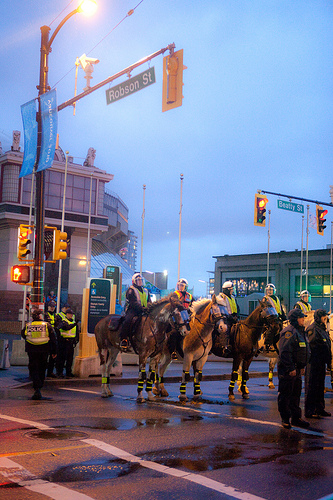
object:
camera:
[74, 51, 99, 76]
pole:
[26, 23, 53, 316]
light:
[74, 0, 105, 25]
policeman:
[123, 273, 149, 355]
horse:
[95, 293, 188, 405]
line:
[0, 408, 262, 500]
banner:
[16, 94, 38, 179]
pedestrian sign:
[9, 263, 36, 286]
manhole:
[20, 422, 94, 442]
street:
[1, 376, 331, 499]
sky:
[185, 3, 331, 180]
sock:
[99, 364, 108, 391]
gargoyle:
[81, 146, 99, 168]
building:
[0, 127, 130, 372]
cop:
[19, 306, 56, 402]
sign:
[104, 67, 155, 105]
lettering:
[107, 66, 156, 106]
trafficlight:
[257, 198, 268, 211]